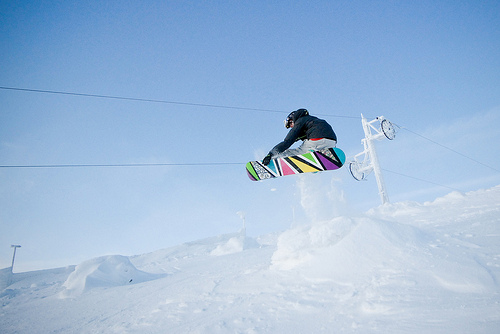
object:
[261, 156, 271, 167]
glove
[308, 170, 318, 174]
glove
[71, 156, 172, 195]
cloud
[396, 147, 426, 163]
cloud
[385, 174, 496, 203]
cloud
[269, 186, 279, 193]
snow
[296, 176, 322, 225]
snow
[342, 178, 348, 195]
snow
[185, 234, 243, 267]
hill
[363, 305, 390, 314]
track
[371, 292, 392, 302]
track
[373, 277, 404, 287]
track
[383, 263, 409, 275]
track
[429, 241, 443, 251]
track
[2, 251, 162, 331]
snow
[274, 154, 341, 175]
rainbow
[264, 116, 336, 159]
coat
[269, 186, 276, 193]
snow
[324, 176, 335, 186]
snow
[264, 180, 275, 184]
snow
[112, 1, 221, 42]
sky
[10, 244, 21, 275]
pole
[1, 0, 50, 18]
air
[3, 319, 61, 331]
ground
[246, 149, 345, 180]
board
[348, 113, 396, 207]
apparatus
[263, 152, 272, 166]
hand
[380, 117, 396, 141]
wheel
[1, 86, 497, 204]
ski lift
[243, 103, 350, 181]
man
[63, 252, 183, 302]
drift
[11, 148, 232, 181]
wire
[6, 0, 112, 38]
sky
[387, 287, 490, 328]
ground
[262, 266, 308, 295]
snow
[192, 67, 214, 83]
air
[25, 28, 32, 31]
clouds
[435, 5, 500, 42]
sky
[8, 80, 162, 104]
wires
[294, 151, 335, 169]
colors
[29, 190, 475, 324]
mountainside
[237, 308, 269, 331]
snow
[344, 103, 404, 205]
device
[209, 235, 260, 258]
mountain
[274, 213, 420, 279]
snow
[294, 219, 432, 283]
mountain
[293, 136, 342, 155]
pants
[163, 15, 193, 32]
air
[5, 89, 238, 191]
lifts